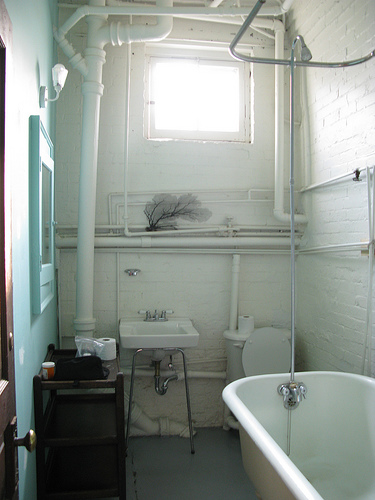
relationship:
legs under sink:
[126, 348, 195, 455] [118, 318, 199, 345]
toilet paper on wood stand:
[96, 337, 116, 359] [33, 342, 126, 498]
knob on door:
[14, 429, 37, 452] [2, 26, 29, 480]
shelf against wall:
[49, 343, 117, 489] [13, 207, 22, 217]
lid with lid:
[241, 326, 292, 376] [246, 334, 293, 374]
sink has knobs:
[117, 309, 200, 348] [164, 310, 175, 319]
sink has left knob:
[117, 309, 200, 348] [132, 308, 146, 317]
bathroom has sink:
[2, 5, 371, 496] [117, 320, 202, 348]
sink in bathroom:
[117, 320, 202, 348] [2, 5, 371, 496]